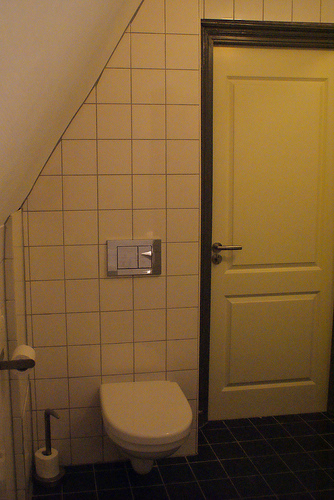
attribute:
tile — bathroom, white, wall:
[73, 300, 187, 362]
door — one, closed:
[202, 29, 332, 433]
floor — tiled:
[228, 439, 317, 499]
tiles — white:
[127, 328, 142, 356]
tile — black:
[67, 409, 329, 496]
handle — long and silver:
[215, 245, 242, 249]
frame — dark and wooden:
[197, 424, 204, 443]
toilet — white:
[119, 401, 160, 422]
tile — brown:
[122, 430, 315, 493]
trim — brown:
[189, 307, 221, 438]